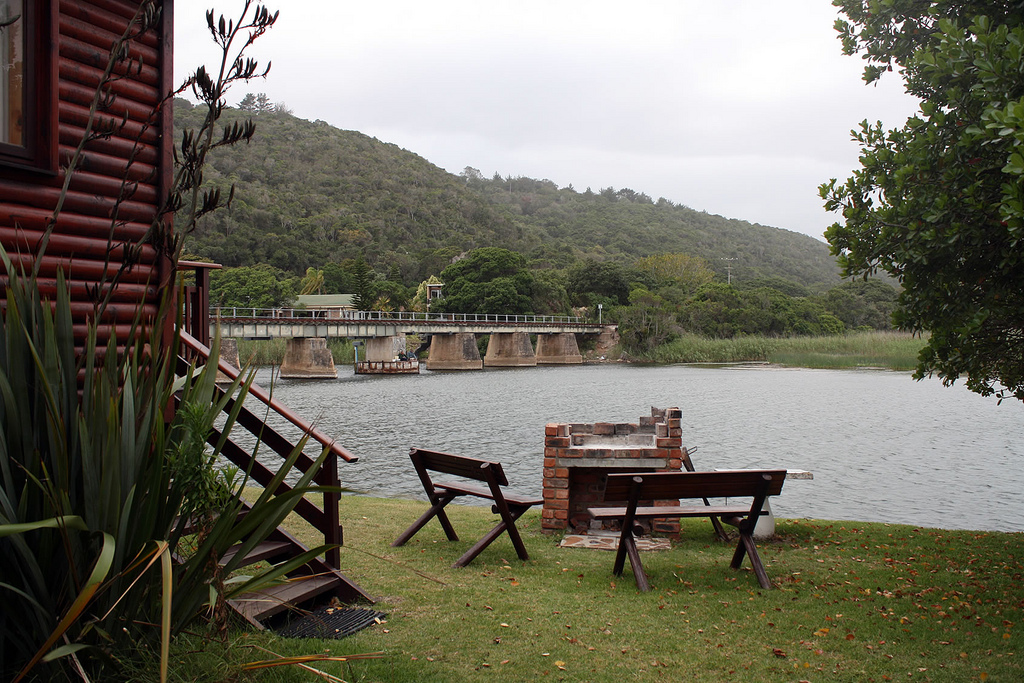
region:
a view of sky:
[498, 76, 642, 157]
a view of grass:
[541, 579, 649, 659]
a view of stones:
[767, 544, 955, 669]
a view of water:
[755, 401, 921, 484]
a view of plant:
[878, 310, 1006, 393]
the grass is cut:
[133, 480, 1020, 677]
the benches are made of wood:
[588, 474, 785, 596]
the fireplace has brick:
[540, 407, 678, 535]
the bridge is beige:
[201, 319, 606, 384]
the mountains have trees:
[180, 100, 926, 332]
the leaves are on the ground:
[344, 525, 1021, 677]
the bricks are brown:
[543, 407, 676, 528]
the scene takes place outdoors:
[0, 3, 1019, 680]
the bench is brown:
[589, 466, 783, 590]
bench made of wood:
[400, 447, 538, 568]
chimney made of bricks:
[538, 407, 684, 544]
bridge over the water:
[206, 308, 625, 382]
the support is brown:
[277, 337, 332, 377]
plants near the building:
[5, 0, 363, 680]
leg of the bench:
[626, 540, 650, 591]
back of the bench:
[409, 447, 505, 486]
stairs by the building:
[174, 327, 370, 644]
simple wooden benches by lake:
[397, 445, 784, 578]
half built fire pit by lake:
[545, 407, 685, 534]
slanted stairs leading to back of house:
[172, 316, 392, 650]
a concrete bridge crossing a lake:
[172, 288, 641, 378]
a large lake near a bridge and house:
[254, 360, 1022, 525]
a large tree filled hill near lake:
[175, 89, 925, 327]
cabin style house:
[0, 0, 179, 481]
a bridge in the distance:
[207, 276, 634, 382]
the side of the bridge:
[209, 299, 611, 375]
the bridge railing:
[210, 292, 603, 322]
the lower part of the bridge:
[209, 337, 598, 357]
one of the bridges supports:
[270, 334, 347, 380]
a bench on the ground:
[586, 457, 787, 593]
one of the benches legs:
[459, 514, 502, 575]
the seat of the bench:
[586, 494, 774, 521]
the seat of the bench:
[430, 471, 533, 510]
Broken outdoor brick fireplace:
[541, 404, 685, 540]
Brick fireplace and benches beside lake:
[389, 404, 783, 591]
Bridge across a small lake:
[177, 297, 662, 386]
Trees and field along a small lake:
[698, 274, 1022, 431]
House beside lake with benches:
[25, 47, 847, 576]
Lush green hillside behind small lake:
[190, 89, 830, 383]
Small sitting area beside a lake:
[376, 399, 864, 652]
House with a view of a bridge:
[27, 99, 862, 660]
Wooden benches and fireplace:
[384, 399, 834, 633]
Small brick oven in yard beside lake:
[381, 404, 849, 607]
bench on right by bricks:
[567, 453, 801, 612]